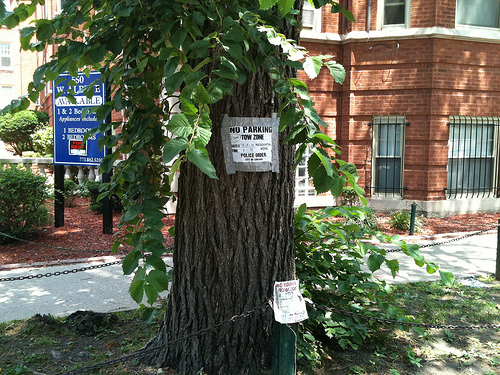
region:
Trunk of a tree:
[159, 0, 314, 370]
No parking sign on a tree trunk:
[216, 108, 289, 183]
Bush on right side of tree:
[283, 196, 468, 356]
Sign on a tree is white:
[268, 276, 315, 332]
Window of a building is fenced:
[439, 109, 499, 204]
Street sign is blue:
[33, 61, 122, 244]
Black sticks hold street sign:
[42, 168, 119, 240]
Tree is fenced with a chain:
[0, 224, 494, 285]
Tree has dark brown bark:
[159, 11, 317, 372]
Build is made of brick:
[302, 4, 499, 224]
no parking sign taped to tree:
[226, 110, 278, 179]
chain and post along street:
[57, 296, 497, 366]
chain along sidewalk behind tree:
[1, 252, 176, 282]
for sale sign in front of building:
[38, 66, 117, 239]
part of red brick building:
[303, 7, 499, 207]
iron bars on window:
[370, 114, 407, 200]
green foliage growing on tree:
[41, 1, 444, 311]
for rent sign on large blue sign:
[65, 136, 92, 158]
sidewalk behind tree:
[2, 255, 167, 320]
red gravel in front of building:
[16, 195, 178, 260]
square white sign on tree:
[238, 245, 318, 352]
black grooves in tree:
[205, 219, 249, 319]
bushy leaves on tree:
[305, 173, 420, 337]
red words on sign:
[50, 133, 104, 178]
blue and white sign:
[30, 53, 117, 197]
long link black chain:
[8, 259, 230, 299]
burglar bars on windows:
[442, 107, 499, 228]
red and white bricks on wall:
[360, 43, 455, 95]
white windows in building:
[371, 3, 427, 35]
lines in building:
[358, 51, 480, 121]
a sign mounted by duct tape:
[217, 105, 288, 181]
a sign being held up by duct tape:
[217, 109, 281, 178]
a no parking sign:
[219, 109, 286, 184]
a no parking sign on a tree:
[213, 108, 283, 180]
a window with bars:
[362, 110, 422, 211]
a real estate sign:
[49, 67, 111, 168]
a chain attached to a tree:
[85, 300, 268, 373]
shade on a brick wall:
[344, 14, 496, 199]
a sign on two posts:
[51, 67, 115, 234]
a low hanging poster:
[264, 274, 310, 336]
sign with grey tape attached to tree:
[153, 87, 319, 213]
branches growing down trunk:
[101, 45, 221, 317]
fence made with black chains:
[15, 220, 495, 355]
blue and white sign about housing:
[35, 52, 130, 187]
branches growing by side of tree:
[276, 205, 436, 367]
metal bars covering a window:
[440, 101, 495, 201]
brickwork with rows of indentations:
[345, 41, 450, 116]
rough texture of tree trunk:
[185, 175, 260, 355]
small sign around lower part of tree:
[260, 265, 322, 367]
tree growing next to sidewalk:
[21, 206, 387, 321]